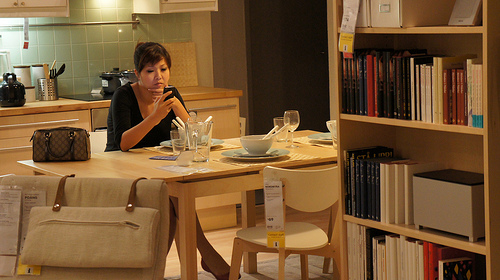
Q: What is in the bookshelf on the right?
A: The book is in the bookshelf.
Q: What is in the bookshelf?
A: The book is in the bookshelf.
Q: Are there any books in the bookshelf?
A: Yes, there is a book in the bookshelf.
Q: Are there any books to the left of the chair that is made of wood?
A: No, the book is to the right of the chair.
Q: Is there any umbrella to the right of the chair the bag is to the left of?
A: No, there is a book to the right of the chair.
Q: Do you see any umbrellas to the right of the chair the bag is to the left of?
A: No, there is a book to the right of the chair.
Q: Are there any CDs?
A: No, there are no cds.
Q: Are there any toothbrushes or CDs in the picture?
A: No, there are no CDs or toothbrushes.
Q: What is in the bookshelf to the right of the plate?
A: The book is in the bookshelf.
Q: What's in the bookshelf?
A: The book is in the bookshelf.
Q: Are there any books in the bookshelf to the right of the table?
A: Yes, there is a book in the bookshelf.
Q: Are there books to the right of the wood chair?
A: Yes, there is a book to the right of the chair.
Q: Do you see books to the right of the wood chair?
A: Yes, there is a book to the right of the chair.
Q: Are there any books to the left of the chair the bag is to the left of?
A: No, the book is to the right of the chair.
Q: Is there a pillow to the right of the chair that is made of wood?
A: No, there is a book to the right of the chair.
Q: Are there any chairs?
A: Yes, there is a chair.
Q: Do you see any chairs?
A: Yes, there is a chair.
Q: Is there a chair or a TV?
A: Yes, there is a chair.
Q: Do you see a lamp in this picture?
A: No, there are no lamps.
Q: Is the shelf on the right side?
A: Yes, the shelf is on the right of the image.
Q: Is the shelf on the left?
A: No, the shelf is on the right of the image.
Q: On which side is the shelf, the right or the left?
A: The shelf is on the right of the image.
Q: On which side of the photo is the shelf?
A: The shelf is on the right of the image.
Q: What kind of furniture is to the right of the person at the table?
A: The piece of furniture is a shelf.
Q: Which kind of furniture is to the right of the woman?
A: The piece of furniture is a shelf.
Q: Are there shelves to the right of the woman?
A: Yes, there is a shelf to the right of the woman.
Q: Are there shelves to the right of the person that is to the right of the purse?
A: Yes, there is a shelf to the right of the woman.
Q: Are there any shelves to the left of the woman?
A: No, the shelf is to the right of the woman.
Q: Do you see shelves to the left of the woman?
A: No, the shelf is to the right of the woman.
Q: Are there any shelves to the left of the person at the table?
A: No, the shelf is to the right of the woman.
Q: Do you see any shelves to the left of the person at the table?
A: No, the shelf is to the right of the woman.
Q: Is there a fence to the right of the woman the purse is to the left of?
A: No, there is a shelf to the right of the woman.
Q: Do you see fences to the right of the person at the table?
A: No, there is a shelf to the right of the woman.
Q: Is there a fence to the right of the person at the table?
A: No, there is a shelf to the right of the woman.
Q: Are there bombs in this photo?
A: No, there are no bombs.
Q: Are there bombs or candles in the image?
A: No, there are no bombs or candles.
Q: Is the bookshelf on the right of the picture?
A: Yes, the bookshelf is on the right of the image.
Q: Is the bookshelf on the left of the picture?
A: No, the bookshelf is on the right of the image.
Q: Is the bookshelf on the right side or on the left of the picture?
A: The bookshelf is on the right of the image.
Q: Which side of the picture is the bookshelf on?
A: The bookshelf is on the right of the image.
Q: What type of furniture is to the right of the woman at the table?
A: The piece of furniture is a bookshelf.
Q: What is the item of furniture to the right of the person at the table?
A: The piece of furniture is a bookshelf.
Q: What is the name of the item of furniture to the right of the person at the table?
A: The piece of furniture is a bookshelf.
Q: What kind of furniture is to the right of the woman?
A: The piece of furniture is a bookshelf.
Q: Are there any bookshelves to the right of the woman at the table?
A: Yes, there is a bookshelf to the right of the woman.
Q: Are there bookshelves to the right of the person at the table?
A: Yes, there is a bookshelf to the right of the woman.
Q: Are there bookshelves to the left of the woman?
A: No, the bookshelf is to the right of the woman.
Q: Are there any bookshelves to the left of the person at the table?
A: No, the bookshelf is to the right of the woman.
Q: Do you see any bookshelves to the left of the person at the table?
A: No, the bookshelf is to the right of the woman.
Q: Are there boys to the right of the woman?
A: No, there is a bookshelf to the right of the woman.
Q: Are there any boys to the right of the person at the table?
A: No, there is a bookshelf to the right of the woman.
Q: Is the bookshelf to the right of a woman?
A: Yes, the bookshelf is to the right of a woman.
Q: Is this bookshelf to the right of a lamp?
A: No, the bookshelf is to the right of a woman.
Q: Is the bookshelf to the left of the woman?
A: No, the bookshelf is to the right of the woman.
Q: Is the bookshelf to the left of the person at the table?
A: No, the bookshelf is to the right of the woman.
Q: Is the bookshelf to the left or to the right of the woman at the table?
A: The bookshelf is to the right of the woman.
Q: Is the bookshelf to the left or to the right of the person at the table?
A: The bookshelf is to the right of the woman.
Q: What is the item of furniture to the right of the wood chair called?
A: The piece of furniture is a bookshelf.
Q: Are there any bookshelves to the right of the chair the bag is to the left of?
A: Yes, there is a bookshelf to the right of the chair.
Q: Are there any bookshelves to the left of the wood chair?
A: No, the bookshelf is to the right of the chair.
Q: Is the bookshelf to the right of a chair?
A: Yes, the bookshelf is to the right of a chair.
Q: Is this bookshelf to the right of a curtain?
A: No, the bookshelf is to the right of a chair.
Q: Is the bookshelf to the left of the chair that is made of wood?
A: No, the bookshelf is to the right of the chair.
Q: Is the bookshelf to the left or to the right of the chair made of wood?
A: The bookshelf is to the right of the chair.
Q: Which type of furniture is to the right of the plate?
A: The piece of furniture is a bookshelf.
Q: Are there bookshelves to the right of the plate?
A: Yes, there is a bookshelf to the right of the plate.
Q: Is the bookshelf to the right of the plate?
A: Yes, the bookshelf is to the right of the plate.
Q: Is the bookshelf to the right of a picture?
A: No, the bookshelf is to the right of the plate.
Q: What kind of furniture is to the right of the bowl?
A: The piece of furniture is a bookshelf.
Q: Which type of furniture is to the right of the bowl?
A: The piece of furniture is a bookshelf.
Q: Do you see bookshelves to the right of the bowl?
A: Yes, there is a bookshelf to the right of the bowl.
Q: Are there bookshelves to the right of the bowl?
A: Yes, there is a bookshelf to the right of the bowl.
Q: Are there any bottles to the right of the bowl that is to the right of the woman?
A: No, there is a bookshelf to the right of the bowl.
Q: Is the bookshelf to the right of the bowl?
A: Yes, the bookshelf is to the right of the bowl.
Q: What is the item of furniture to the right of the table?
A: The piece of furniture is a bookshelf.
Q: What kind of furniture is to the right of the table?
A: The piece of furniture is a bookshelf.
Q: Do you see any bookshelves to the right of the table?
A: Yes, there is a bookshelf to the right of the table.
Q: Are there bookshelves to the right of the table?
A: Yes, there is a bookshelf to the right of the table.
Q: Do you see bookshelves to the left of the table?
A: No, the bookshelf is to the right of the table.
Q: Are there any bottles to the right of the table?
A: No, there is a bookshelf to the right of the table.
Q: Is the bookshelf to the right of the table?
A: Yes, the bookshelf is to the right of the table.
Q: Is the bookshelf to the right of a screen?
A: No, the bookshelf is to the right of the table.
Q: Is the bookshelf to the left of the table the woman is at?
A: No, the bookshelf is to the right of the table.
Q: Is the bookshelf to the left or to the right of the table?
A: The bookshelf is to the right of the table.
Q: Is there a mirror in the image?
A: No, there are no mirrors.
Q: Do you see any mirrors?
A: No, there are no mirrors.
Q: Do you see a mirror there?
A: No, there are no mirrors.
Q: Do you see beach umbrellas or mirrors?
A: No, there are no mirrors or beach umbrellas.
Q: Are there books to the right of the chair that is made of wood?
A: Yes, there is a book to the right of the chair.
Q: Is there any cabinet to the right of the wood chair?
A: No, there is a book to the right of the chair.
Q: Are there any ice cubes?
A: No, there are no ice cubes.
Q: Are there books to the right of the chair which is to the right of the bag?
A: Yes, there is a book to the right of the chair.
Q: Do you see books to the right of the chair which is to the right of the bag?
A: Yes, there is a book to the right of the chair.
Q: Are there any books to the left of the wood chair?
A: No, the book is to the right of the chair.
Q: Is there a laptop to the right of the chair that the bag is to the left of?
A: No, there is a book to the right of the chair.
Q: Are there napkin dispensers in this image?
A: No, there are no napkin dispensers.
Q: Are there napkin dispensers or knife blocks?
A: No, there are no napkin dispensers or knife blocks.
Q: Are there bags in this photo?
A: Yes, there is a bag.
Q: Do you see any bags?
A: Yes, there is a bag.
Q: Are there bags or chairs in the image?
A: Yes, there is a bag.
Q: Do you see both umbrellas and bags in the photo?
A: No, there is a bag but no umbrellas.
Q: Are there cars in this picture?
A: No, there are no cars.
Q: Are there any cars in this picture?
A: No, there are no cars.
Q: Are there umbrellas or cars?
A: No, there are no cars or umbrellas.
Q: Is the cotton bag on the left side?
A: Yes, the bag is on the left of the image.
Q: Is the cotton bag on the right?
A: No, the bag is on the left of the image.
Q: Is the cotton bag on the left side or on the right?
A: The bag is on the left of the image.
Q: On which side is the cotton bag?
A: The bag is on the left of the image.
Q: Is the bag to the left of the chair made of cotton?
A: Yes, the bag is made of cotton.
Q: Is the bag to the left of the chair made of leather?
A: No, the bag is made of cotton.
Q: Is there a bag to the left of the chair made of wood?
A: Yes, there is a bag to the left of the chair.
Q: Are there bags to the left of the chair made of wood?
A: Yes, there is a bag to the left of the chair.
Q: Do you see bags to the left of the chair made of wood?
A: Yes, there is a bag to the left of the chair.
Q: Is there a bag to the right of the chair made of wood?
A: No, the bag is to the left of the chair.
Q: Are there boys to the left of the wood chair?
A: No, there is a bag to the left of the chair.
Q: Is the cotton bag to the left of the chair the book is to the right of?
A: Yes, the bag is to the left of the chair.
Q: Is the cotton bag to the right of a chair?
A: No, the bag is to the left of a chair.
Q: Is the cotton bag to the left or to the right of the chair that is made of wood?
A: The bag is to the left of the chair.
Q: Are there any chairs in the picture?
A: Yes, there is a chair.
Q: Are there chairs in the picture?
A: Yes, there is a chair.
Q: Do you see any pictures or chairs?
A: Yes, there is a chair.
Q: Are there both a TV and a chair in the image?
A: No, there is a chair but no televisions.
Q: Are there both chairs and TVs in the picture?
A: No, there is a chair but no televisions.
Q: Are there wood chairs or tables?
A: Yes, there is a wood chair.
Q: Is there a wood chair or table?
A: Yes, there is a wood chair.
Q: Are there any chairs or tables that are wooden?
A: Yes, the chair is wooden.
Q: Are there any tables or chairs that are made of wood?
A: Yes, the chair is made of wood.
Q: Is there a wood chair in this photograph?
A: Yes, there is a wood chair.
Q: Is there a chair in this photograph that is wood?
A: Yes, there is a wood chair.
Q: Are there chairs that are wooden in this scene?
A: Yes, there is a wood chair.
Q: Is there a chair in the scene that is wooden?
A: Yes, there is a chair that is wooden.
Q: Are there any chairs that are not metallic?
A: Yes, there is a wooden chair.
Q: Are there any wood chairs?
A: Yes, there is a chair that is made of wood.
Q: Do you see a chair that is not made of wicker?
A: Yes, there is a chair that is made of wood.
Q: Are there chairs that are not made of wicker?
A: Yes, there is a chair that is made of wood.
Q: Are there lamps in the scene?
A: No, there are no lamps.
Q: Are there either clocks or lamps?
A: No, there are no lamps or clocks.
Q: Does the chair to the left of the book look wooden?
A: Yes, the chair is wooden.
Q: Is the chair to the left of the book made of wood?
A: Yes, the chair is made of wood.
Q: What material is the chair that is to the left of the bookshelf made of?
A: The chair is made of wood.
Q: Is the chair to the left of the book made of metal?
A: No, the chair is made of wood.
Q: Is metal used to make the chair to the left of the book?
A: No, the chair is made of wood.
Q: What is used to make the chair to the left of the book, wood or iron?
A: The chair is made of wood.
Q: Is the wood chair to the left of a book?
A: Yes, the chair is to the left of a book.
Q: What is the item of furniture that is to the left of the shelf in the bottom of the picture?
A: The piece of furniture is a chair.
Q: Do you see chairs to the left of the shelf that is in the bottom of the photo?
A: Yes, there is a chair to the left of the shelf.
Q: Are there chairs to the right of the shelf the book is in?
A: No, the chair is to the left of the shelf.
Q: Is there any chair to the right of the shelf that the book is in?
A: No, the chair is to the left of the shelf.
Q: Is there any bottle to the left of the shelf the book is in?
A: No, there is a chair to the left of the shelf.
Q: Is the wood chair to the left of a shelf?
A: Yes, the chair is to the left of a shelf.